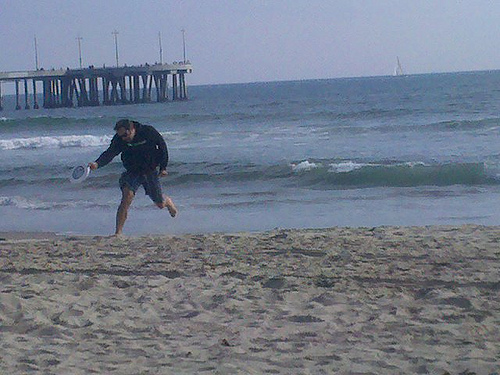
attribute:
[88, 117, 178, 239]
man — shoeless, playing, bending, catching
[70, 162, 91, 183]
frisbee — round, white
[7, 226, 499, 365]
sand — filled, everywhere, on, divoted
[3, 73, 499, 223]
water — breaking, blue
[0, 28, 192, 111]
pier — large, above, bridgelike, long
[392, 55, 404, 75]
sail boat — white, sailing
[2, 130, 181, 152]
wave — small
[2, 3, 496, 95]
sky — blue, background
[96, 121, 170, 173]
hoodie — black